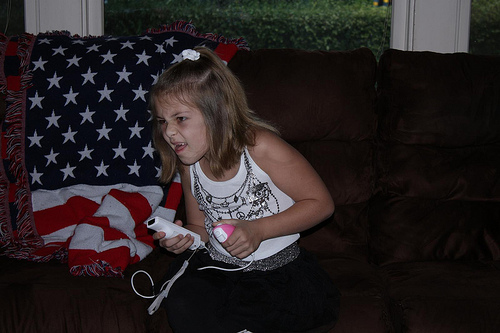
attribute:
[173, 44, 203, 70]
hair band — white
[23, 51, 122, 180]
stars — white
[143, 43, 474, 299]
couch — brown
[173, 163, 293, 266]
tank top — graphic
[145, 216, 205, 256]
wii remote — white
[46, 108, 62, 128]
star — WHITE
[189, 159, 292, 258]
top — white 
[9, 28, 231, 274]
flag — RED , WHITE, BLUE 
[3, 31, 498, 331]
sofa — BROWN 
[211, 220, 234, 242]
controller — PINK 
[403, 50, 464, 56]
frame — white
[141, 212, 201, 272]
will — white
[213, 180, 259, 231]
shirt — white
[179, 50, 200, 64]
band — white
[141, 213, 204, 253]
remote —  white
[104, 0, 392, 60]
leaves — green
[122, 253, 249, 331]
wire — white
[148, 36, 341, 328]
girl — little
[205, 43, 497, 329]
couch — brown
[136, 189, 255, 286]
remote control — wii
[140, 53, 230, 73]
hair holder — white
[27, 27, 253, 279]
flag — red, white, blue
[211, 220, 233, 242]
wii — pink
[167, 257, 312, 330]
pant — black